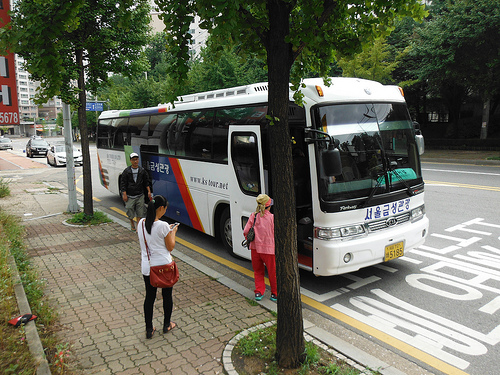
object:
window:
[128, 114, 154, 153]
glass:
[238, 139, 252, 185]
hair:
[141, 194, 169, 236]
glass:
[216, 109, 256, 123]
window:
[98, 118, 115, 146]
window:
[214, 108, 231, 167]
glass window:
[151, 111, 185, 152]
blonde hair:
[256, 193, 270, 215]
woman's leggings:
[144, 273, 172, 335]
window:
[127, 114, 150, 155]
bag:
[139, 217, 183, 290]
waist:
[142, 246, 177, 266]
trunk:
[263, 7, 315, 368]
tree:
[191, 0, 427, 369]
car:
[47, 142, 84, 167]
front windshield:
[315, 98, 425, 203]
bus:
[94, 75, 434, 277]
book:
[13, 312, 33, 330]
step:
[0, 220, 57, 374]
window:
[173, 108, 216, 160]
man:
[118, 151, 155, 234]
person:
[241, 192, 288, 301]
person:
[136, 192, 180, 339]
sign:
[82, 99, 106, 112]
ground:
[0, 134, 500, 374]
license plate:
[381, 239, 409, 263]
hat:
[130, 151, 142, 160]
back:
[137, 217, 168, 272]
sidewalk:
[0, 148, 475, 374]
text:
[186, 174, 228, 193]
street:
[9, 137, 500, 374]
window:
[228, 127, 263, 195]